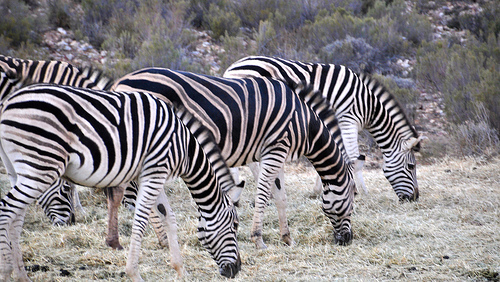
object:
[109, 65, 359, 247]
zebra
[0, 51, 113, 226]
zebra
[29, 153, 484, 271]
grass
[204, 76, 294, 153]
pattern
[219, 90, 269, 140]
fur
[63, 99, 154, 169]
fur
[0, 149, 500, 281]
field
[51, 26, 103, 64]
rocks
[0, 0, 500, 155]
hill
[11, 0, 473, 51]
hill top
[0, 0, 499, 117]
bushes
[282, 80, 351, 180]
mane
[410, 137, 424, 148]
ear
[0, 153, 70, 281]
leg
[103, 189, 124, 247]
leg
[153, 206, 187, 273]
leg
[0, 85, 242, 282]
zebra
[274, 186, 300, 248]
leg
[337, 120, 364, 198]
leg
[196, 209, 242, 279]
head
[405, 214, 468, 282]
ground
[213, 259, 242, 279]
nose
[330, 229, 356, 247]
nose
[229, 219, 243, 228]
eye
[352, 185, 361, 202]
eye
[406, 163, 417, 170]
eye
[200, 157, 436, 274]
grazing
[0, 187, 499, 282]
grass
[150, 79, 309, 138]
stripes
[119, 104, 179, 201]
stripes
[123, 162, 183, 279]
legs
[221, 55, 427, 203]
zebra